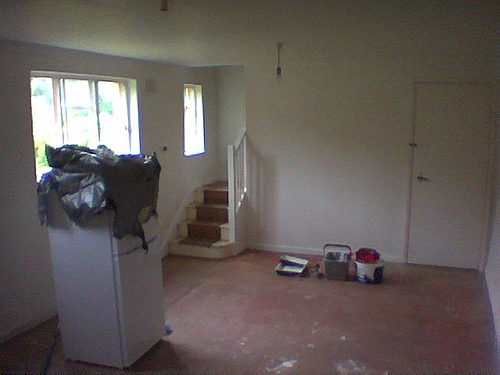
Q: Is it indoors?
A: Yes, it is indoors.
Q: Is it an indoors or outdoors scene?
A: It is indoors.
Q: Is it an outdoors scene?
A: No, it is indoors.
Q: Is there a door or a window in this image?
A: Yes, there is a window.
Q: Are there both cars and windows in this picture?
A: No, there is a window but no cars.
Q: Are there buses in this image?
A: No, there are no buses.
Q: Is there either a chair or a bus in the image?
A: No, there are no buses or chairs.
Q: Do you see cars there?
A: No, there are no cars.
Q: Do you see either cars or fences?
A: No, there are no cars or fences.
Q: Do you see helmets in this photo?
A: No, there are no helmets.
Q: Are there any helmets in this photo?
A: No, there are no helmets.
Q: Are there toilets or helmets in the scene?
A: No, there are no helmets or toilets.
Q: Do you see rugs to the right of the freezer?
A: Yes, there is a rug to the right of the freezer.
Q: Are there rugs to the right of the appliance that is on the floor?
A: Yes, there is a rug to the right of the freezer.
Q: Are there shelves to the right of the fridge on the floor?
A: No, there is a rug to the right of the freezer.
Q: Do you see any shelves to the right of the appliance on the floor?
A: No, there is a rug to the right of the freezer.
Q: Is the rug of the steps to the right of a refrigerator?
A: Yes, the rug is to the right of a refrigerator.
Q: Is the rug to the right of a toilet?
A: No, the rug is to the right of a refrigerator.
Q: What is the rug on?
A: The rug is on the steps.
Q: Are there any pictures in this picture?
A: No, there are no pictures.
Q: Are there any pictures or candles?
A: No, there are no pictures or candles.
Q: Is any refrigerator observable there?
A: Yes, there is a refrigerator.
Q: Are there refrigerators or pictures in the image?
A: Yes, there is a refrigerator.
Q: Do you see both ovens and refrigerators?
A: No, there is a refrigerator but no ovens.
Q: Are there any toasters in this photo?
A: No, there are no toasters.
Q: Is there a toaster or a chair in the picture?
A: No, there are no toasters or chairs.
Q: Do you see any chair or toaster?
A: No, there are no toasters or chairs.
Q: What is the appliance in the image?
A: The appliance is a refrigerator.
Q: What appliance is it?
A: The appliance is a refrigerator.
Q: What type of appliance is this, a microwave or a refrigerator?
A: This is a refrigerator.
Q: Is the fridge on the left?
A: Yes, the fridge is on the left of the image.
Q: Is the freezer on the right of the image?
A: No, the freezer is on the left of the image.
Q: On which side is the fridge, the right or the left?
A: The fridge is on the left of the image.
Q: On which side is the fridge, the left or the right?
A: The fridge is on the left of the image.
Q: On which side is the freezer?
A: The freezer is on the left of the image.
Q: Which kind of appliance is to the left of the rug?
A: The appliance is a refrigerator.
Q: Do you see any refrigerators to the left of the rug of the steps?
A: Yes, there is a refrigerator to the left of the rug.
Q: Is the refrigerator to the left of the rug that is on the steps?
A: Yes, the refrigerator is to the left of the rug.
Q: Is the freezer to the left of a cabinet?
A: No, the freezer is to the left of the rug.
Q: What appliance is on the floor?
A: The appliance is a refrigerator.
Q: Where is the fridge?
A: The fridge is on the floor.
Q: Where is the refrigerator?
A: The fridge is on the floor.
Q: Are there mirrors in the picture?
A: No, there are no mirrors.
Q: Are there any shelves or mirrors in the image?
A: No, there are no mirrors or shelves.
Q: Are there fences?
A: No, there are no fences.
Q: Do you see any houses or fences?
A: No, there are no fences or houses.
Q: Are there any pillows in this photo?
A: No, there are no pillows.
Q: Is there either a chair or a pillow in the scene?
A: No, there are no pillows or chairs.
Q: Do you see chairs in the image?
A: No, there are no chairs.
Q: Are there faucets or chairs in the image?
A: No, there are no chairs or faucets.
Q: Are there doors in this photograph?
A: Yes, there is a door.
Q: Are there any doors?
A: Yes, there is a door.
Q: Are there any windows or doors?
A: Yes, there is a door.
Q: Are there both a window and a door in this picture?
A: Yes, there are both a door and a window.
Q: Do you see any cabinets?
A: No, there are no cabinets.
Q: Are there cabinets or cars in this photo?
A: No, there are no cabinets or cars.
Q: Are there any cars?
A: No, there are no cars.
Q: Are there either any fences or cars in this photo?
A: No, there are no cars or fences.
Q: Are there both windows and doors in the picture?
A: Yes, there are both a window and a door.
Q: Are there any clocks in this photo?
A: No, there are no clocks.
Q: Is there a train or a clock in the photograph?
A: No, there are no clocks or trains.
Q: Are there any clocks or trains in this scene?
A: No, there are no clocks or trains.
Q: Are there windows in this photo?
A: Yes, there is a window.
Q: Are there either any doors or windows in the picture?
A: Yes, there is a window.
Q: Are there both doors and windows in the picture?
A: Yes, there are both a window and a door.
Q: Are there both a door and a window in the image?
A: Yes, there are both a window and a door.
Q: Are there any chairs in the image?
A: No, there are no chairs.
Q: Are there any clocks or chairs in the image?
A: No, there are no chairs or clocks.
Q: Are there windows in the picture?
A: Yes, there is a window.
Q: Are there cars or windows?
A: Yes, there is a window.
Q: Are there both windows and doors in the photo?
A: Yes, there are both a window and a door.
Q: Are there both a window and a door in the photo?
A: Yes, there are both a window and a door.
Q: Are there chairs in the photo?
A: No, there are no chairs.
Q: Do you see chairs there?
A: No, there are no chairs.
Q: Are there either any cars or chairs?
A: No, there are no chairs or cars.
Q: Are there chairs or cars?
A: No, there are no chairs or cars.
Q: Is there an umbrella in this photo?
A: No, there are no umbrellas.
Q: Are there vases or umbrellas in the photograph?
A: No, there are no umbrellas or vases.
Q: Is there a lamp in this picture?
A: No, there are no lamps.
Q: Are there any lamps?
A: No, there are no lamps.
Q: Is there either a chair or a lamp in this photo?
A: No, there are no lamps or chairs.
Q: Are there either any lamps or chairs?
A: No, there are no lamps or chairs.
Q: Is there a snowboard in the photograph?
A: No, there are no snowboards.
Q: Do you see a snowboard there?
A: No, there are no snowboards.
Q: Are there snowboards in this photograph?
A: No, there are no snowboards.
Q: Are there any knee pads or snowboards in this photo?
A: No, there are no snowboards or knee pads.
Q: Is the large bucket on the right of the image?
A: Yes, the bucket is on the right of the image.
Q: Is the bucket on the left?
A: No, the bucket is on the right of the image.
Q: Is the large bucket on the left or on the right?
A: The bucket is on the right of the image.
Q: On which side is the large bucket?
A: The bucket is on the right of the image.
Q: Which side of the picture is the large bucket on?
A: The bucket is on the right of the image.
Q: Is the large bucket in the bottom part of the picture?
A: Yes, the bucket is in the bottom of the image.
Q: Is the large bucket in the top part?
A: No, the bucket is in the bottom of the image.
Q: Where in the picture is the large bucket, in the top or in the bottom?
A: The bucket is in the bottom of the image.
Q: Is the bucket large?
A: Yes, the bucket is large.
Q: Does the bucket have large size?
A: Yes, the bucket is large.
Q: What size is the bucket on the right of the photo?
A: The bucket is large.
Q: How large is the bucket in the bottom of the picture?
A: The bucket is large.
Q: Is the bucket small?
A: No, the bucket is large.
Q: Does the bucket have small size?
A: No, the bucket is large.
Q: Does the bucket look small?
A: No, the bucket is large.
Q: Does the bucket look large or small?
A: The bucket is large.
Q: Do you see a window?
A: Yes, there are windows.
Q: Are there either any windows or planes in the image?
A: Yes, there are windows.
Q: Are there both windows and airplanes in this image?
A: No, there are windows but no airplanes.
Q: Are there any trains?
A: No, there are no trains.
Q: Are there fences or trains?
A: No, there are no trains or fences.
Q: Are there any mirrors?
A: No, there are no mirrors.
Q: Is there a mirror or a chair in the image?
A: No, there are no mirrors or chairs.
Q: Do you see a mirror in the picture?
A: No, there are no mirrors.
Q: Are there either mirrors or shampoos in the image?
A: No, there are no mirrors or shampoos.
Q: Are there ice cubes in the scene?
A: No, there are no ice cubes.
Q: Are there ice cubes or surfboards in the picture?
A: No, there are no ice cubes or surfboards.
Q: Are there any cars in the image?
A: No, there are no cars.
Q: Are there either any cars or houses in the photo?
A: No, there are no cars or houses.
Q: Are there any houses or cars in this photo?
A: No, there are no cars or houses.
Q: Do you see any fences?
A: No, there are no fences.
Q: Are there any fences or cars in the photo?
A: No, there are no fences or cars.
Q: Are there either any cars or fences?
A: No, there are no fences or cars.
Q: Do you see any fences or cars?
A: No, there are no fences or cars.